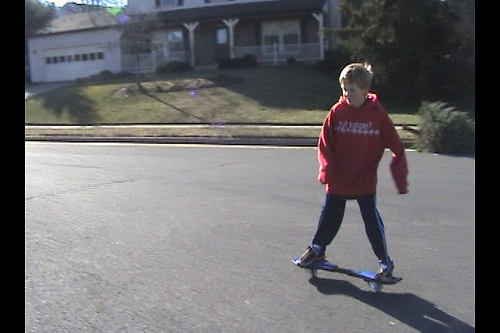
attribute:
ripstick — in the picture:
[281, 242, 399, 287]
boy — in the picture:
[296, 61, 408, 278]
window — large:
[262, 21, 282, 54]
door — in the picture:
[209, 22, 235, 72]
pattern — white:
[336, 115, 379, 137]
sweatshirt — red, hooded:
[310, 99, 410, 206]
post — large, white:
[318, 15, 324, 56]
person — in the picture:
[292, 54, 412, 276]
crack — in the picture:
[26, 147, 313, 206]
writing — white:
[327, 110, 387, 140]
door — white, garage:
[31, 32, 133, 99]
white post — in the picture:
[228, 17, 235, 60]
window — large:
[167, 30, 184, 56]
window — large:
[261, 20, 306, 54]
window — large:
[272, 33, 309, 50]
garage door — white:
[27, 33, 135, 88]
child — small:
[299, 61, 410, 281]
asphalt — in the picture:
[31, 142, 493, 327]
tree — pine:
[402, 98, 474, 156]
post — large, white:
[182, 18, 202, 60]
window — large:
[164, 27, 188, 63]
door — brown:
[191, 20, 217, 67]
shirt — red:
[316, 93, 409, 199]